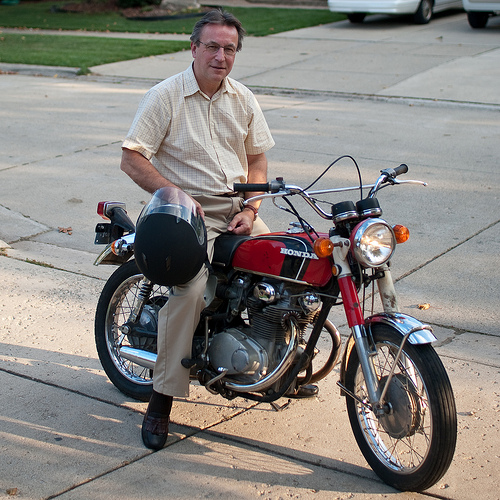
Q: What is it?
A: Bike.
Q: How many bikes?
A: 1.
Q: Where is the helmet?
A: Handle bars.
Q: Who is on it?
A: The man.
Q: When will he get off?
A: Soon.